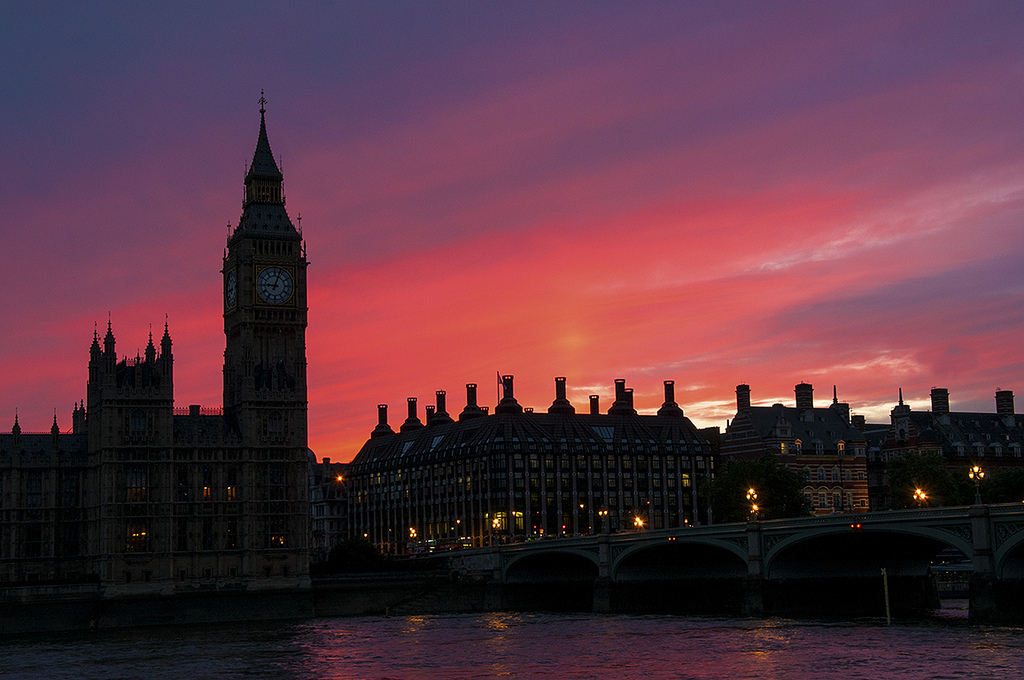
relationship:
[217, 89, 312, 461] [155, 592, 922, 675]
building by river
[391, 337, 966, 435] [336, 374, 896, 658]
chimneys on buildings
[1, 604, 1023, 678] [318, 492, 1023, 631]
river under bridge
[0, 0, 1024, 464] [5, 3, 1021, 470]
cloud area in sky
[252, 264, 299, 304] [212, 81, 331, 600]
clock on tower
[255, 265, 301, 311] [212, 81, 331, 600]
clock on tower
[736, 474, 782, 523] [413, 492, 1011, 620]
light on bridge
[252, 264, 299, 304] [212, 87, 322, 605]
clock on building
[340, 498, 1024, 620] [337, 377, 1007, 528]
bridge between building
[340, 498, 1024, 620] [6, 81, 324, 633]
bridge between building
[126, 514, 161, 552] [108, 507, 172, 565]
light in window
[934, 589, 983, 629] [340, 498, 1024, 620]
sign under bridge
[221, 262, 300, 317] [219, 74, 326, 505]
clock on side of building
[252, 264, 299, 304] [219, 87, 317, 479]
clock on tower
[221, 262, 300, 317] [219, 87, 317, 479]
clock on tower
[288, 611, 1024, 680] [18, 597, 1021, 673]
reflection in river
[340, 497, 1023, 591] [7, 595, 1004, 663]
bridge above water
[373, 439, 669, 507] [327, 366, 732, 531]
windows on building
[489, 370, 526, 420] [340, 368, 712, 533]
flag pole on top of building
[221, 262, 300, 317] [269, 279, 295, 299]
clock has hands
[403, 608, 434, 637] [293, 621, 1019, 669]
light reflection on water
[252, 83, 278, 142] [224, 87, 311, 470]
top of clock tower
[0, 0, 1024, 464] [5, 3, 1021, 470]
cloud area of sky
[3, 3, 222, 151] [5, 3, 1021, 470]
cloud area in sky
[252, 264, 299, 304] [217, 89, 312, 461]
clock in building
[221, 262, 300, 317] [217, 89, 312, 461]
clock in building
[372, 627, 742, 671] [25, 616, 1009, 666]
reflection in water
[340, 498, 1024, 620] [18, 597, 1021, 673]
bridge across river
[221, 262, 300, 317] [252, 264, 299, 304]
clock has clock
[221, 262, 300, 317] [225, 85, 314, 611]
clock in tower